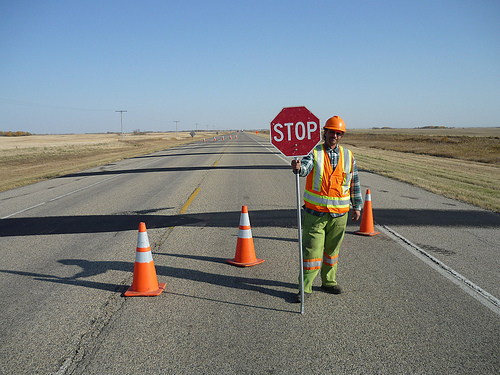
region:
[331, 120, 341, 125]
man wearing orange helmet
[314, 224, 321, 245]
man wearing green pants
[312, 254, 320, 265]
orange stripe on pants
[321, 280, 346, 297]
man wearing black sneakers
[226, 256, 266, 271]
bottom of orange cone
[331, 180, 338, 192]
man wearing orange vest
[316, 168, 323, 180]
grey patch on vest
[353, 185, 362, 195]
blue color on shirt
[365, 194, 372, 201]
white stripe on cone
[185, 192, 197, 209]
yellow line on road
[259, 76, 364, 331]
street worker is holding a stop sign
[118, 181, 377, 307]
cones in the street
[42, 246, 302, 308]
shadow of the man reflected on the street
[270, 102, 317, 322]
stop sign in the man's hand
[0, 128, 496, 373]
open and empty street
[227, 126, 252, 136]
vanishing point for the street and ground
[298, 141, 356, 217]
orange reflecter vest on the man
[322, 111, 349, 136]
the man is wearing an orange hard hat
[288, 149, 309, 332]
metal pole of the stop sign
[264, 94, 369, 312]
man holding stop sign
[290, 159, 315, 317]
pole stop sign attached to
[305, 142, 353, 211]
safety vest man i wearing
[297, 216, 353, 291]
safety pants man is wearing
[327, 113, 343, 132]
orange hard hat helmet man is wearing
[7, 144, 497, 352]
shadows on the road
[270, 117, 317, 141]
white lettering on red background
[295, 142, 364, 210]
plaid long sleeve shirt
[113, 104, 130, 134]
utility pole in the distance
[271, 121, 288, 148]
white letter on sign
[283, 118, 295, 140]
white letter on sign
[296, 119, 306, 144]
white letter on sign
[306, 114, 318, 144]
white letter on sign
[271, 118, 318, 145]
white letters on sign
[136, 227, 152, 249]
white stripe on cone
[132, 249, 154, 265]
white stripe on cone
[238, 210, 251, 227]
white stripe on cone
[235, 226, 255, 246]
white stripe on cone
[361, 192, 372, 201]
white stripe on cone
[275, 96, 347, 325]
a man holding a sign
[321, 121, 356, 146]
a man wearing a orange hard hat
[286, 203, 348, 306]
a man wearing green pants with orange stripes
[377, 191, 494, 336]
a white line painted on a road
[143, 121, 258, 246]
a long straight stretch of a road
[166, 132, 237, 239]
yellow lines painted on a road way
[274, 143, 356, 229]
a man wearing a safety vest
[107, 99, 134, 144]
a electrical pole